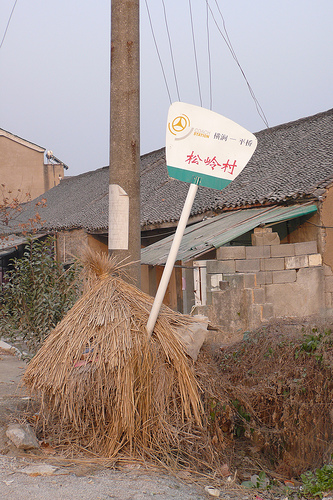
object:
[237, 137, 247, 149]
characters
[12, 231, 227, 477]
straw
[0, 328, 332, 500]
ground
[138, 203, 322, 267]
awning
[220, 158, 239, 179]
characters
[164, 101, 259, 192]
sign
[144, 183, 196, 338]
pole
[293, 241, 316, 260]
brick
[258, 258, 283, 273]
brick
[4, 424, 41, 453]
rock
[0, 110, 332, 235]
roof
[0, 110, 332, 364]
house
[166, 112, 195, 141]
symbol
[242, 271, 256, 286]
brick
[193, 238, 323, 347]
wall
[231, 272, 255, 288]
brick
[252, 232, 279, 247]
brick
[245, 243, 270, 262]
brick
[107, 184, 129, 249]
paper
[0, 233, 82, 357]
bush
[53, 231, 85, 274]
wall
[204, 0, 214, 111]
wire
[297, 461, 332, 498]
weed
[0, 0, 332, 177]
sky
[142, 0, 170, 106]
wire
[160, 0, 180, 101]
wire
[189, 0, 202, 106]
wire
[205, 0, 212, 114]
wire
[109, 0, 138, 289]
pole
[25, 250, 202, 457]
haystack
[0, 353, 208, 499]
road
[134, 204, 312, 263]
roof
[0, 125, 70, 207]
building